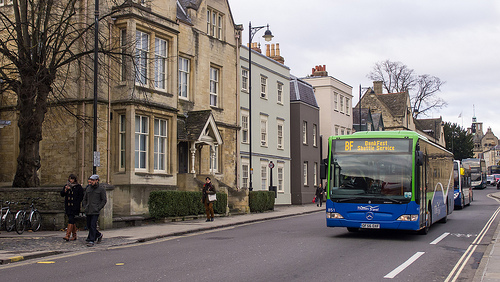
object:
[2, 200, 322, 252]
pavement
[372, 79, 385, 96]
chimney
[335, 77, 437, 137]
house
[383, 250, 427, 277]
broken lines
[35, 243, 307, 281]
road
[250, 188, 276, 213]
hedge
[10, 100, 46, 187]
trunk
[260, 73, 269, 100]
window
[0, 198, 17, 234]
bike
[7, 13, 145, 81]
branches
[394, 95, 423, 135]
ground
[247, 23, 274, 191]
street lamp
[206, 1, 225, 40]
windows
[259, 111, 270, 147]
window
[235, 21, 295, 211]
building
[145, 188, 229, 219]
hedges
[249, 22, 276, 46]
street light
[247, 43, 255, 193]
pole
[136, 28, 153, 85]
window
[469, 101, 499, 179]
building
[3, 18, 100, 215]
tree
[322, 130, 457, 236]
bus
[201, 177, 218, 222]
person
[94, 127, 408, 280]
street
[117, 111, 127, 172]
windows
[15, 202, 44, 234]
bicycle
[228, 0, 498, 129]
cloudy sky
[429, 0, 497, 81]
sky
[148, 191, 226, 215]
bushes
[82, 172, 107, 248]
people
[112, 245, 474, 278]
street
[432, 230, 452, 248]
line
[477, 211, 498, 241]
line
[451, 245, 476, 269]
line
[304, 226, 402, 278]
road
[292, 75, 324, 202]
building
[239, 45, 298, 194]
lighter building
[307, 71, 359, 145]
lighter building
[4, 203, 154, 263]
pavement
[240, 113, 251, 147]
window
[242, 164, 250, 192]
window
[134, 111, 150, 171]
window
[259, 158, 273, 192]
window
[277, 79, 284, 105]
window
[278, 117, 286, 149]
window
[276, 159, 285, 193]
window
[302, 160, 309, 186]
window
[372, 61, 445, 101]
tree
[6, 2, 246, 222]
residence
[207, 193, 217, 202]
bag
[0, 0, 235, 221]
building